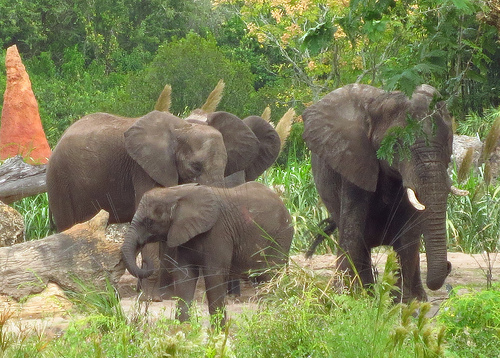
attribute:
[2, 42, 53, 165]
cone — red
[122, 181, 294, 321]
baby — standing, small, center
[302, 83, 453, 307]
elephant — large, adult, walking, standing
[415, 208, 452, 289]
trunk — curled